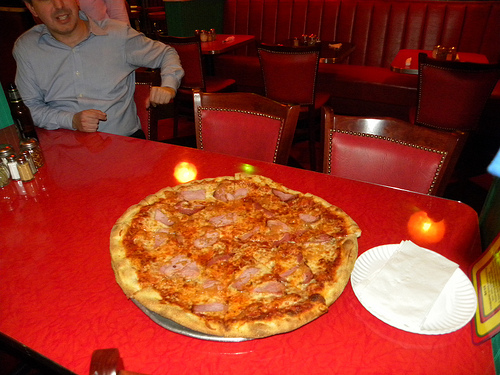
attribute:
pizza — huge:
[109, 172, 366, 339]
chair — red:
[189, 86, 291, 164]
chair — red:
[177, 68, 285, 148]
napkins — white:
[369, 239, 459, 319]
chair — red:
[256, 39, 323, 109]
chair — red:
[413, 49, 494, 138]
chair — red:
[324, 109, 461, 199]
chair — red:
[192, 89, 293, 159]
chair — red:
[157, 34, 237, 89]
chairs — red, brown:
[314, 111, 476, 195]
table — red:
[5, 82, 497, 372]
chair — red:
[174, 89, 339, 198]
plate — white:
[348, 227, 493, 361]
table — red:
[0, 130, 493, 367]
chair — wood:
[326, 74, 467, 215]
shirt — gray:
[50, 60, 126, 97]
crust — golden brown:
[105, 171, 357, 337]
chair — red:
[196, 97, 287, 162]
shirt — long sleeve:
[12, 21, 183, 133]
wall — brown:
[221, 4, 496, 72]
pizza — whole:
[106, 167, 365, 351]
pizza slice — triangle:
[127, 235, 229, 347]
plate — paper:
[335, 214, 492, 345]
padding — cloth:
[324, 128, 444, 189]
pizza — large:
[142, 181, 326, 323]